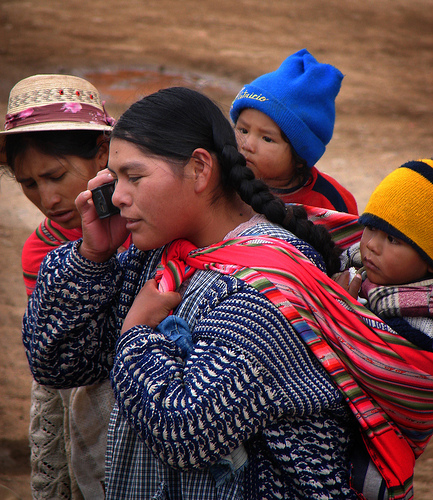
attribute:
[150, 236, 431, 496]
fabric — pink, sling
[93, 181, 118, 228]
phone — black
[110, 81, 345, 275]
hair — dark, braided, braid, black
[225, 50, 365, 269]
child — small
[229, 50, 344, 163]
hat — blue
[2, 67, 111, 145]
hat — patterned, straw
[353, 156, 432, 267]
hat — yellow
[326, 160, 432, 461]
baby — carried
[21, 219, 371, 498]
sweater — blue